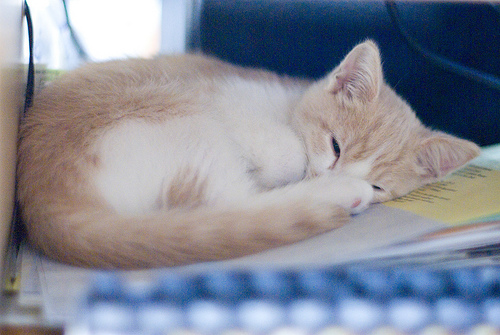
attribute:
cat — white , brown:
[37, 22, 499, 264]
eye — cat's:
[331, 136, 340, 158]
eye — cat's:
[372, 183, 384, 193]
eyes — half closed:
[332, 127, 386, 207]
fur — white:
[29, 91, 91, 212]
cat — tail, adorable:
[17, 36, 478, 266]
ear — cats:
[327, 33, 387, 114]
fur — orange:
[21, 37, 477, 262]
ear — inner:
[335, 39, 386, 107]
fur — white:
[176, 145, 305, 195]